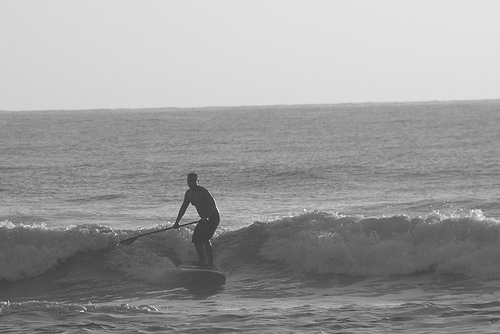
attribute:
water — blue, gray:
[302, 165, 443, 267]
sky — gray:
[174, 10, 280, 60]